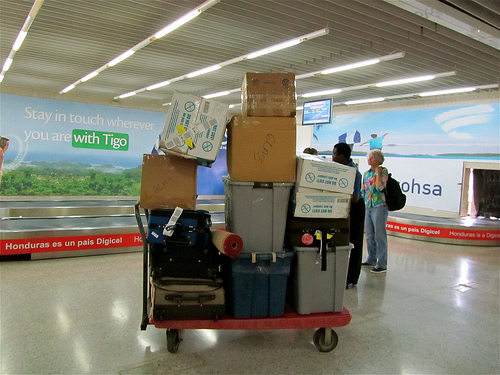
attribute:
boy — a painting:
[360, 132, 390, 150]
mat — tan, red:
[207, 227, 244, 257]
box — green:
[72, 127, 130, 151]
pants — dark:
[350, 197, 367, 289]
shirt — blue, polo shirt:
[340, 161, 363, 197]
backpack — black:
[385, 173, 407, 211]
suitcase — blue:
[147, 207, 211, 245]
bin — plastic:
[224, 176, 294, 253]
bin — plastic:
[231, 252, 294, 319]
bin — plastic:
[296, 244, 352, 315]